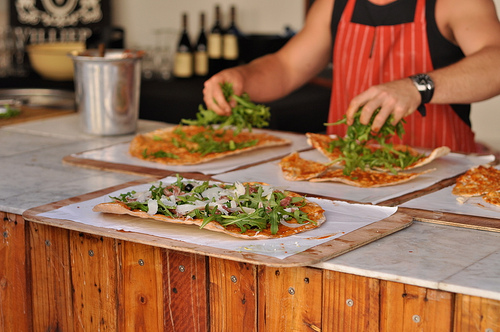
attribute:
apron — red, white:
[327, 1, 478, 153]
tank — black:
[328, 1, 476, 128]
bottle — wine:
[171, 6, 195, 80]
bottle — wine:
[192, 12, 212, 80]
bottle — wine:
[209, 3, 223, 63]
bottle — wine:
[224, 4, 238, 62]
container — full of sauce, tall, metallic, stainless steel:
[67, 35, 141, 136]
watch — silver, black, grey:
[407, 69, 435, 117]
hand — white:
[345, 72, 426, 140]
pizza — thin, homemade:
[120, 117, 288, 169]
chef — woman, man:
[188, 2, 499, 155]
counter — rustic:
[0, 107, 495, 330]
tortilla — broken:
[280, 128, 455, 194]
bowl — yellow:
[22, 37, 94, 90]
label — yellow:
[173, 49, 193, 78]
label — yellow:
[194, 51, 208, 75]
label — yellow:
[208, 31, 221, 62]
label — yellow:
[223, 32, 240, 60]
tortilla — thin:
[87, 170, 330, 252]